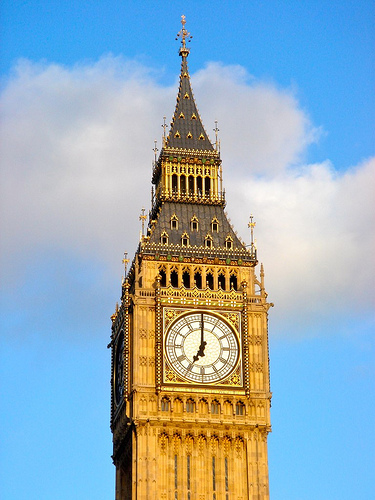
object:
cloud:
[0, 48, 374, 339]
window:
[209, 214, 223, 236]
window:
[189, 213, 199, 235]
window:
[168, 212, 178, 229]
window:
[157, 228, 170, 243]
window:
[224, 232, 234, 247]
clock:
[112, 326, 128, 407]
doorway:
[228, 273, 238, 291]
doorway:
[217, 268, 226, 295]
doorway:
[205, 271, 216, 291]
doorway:
[192, 268, 203, 290]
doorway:
[168, 267, 179, 291]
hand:
[182, 340, 207, 382]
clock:
[155, 297, 249, 398]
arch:
[233, 399, 247, 418]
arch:
[222, 398, 235, 416]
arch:
[210, 396, 221, 413]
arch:
[185, 394, 196, 413]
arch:
[158, 394, 173, 413]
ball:
[179, 48, 189, 57]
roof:
[137, 199, 257, 258]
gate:
[181, 271, 193, 290]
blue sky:
[0, 0, 374, 499]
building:
[106, 13, 275, 499]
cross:
[174, 13, 195, 51]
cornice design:
[131, 251, 267, 309]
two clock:
[110, 297, 252, 426]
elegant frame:
[153, 289, 251, 401]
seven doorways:
[157, 263, 242, 297]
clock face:
[164, 310, 242, 382]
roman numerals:
[196, 364, 206, 385]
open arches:
[157, 265, 167, 290]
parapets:
[159, 159, 223, 203]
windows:
[179, 227, 191, 250]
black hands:
[198, 313, 207, 350]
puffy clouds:
[0, 48, 374, 340]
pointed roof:
[150, 14, 228, 209]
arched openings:
[169, 173, 182, 198]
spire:
[159, 12, 220, 157]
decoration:
[149, 10, 224, 186]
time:
[165, 308, 241, 387]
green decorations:
[256, 289, 268, 298]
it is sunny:
[0, 0, 374, 499]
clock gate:
[152, 302, 251, 401]